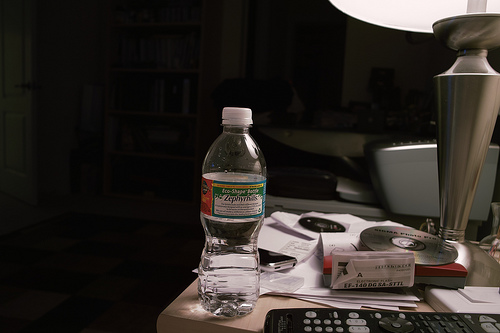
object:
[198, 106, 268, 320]
bottle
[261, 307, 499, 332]
remote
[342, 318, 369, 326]
button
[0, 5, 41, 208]
door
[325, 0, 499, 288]
lamp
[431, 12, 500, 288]
base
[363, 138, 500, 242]
printer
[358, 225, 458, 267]
compact disc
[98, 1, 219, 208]
shelves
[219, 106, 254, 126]
cap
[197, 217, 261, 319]
liquid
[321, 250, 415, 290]
writing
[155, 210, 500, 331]
desk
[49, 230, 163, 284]
rug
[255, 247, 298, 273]
cellphone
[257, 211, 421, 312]
paper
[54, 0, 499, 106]
wall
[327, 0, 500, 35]
shade